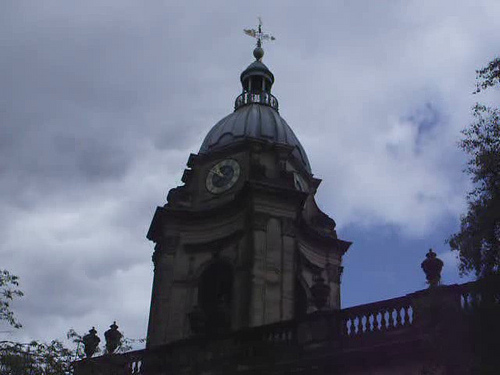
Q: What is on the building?
A: A clock.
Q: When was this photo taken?
A: During the day.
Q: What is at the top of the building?
A: A dome.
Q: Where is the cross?
A: At the very top.